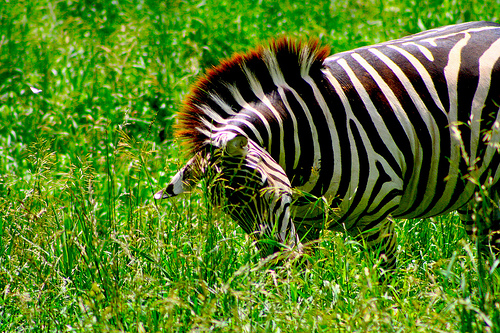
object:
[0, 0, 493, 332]
grass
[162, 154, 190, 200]
edge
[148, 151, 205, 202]
ear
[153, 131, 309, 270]
head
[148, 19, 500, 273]
zebra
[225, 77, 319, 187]
neck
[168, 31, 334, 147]
mane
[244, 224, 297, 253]
nose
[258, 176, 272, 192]
eye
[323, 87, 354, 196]
stripe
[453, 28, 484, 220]
stripe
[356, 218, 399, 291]
leg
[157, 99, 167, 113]
flower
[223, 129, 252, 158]
ear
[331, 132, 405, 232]
shoulder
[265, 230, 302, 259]
jaw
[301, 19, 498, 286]
body